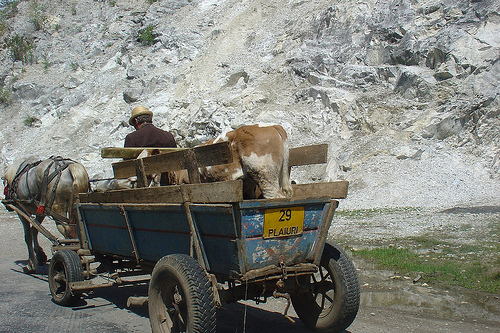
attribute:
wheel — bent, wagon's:
[285, 237, 360, 332]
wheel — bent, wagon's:
[144, 250, 215, 332]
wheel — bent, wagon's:
[46, 246, 86, 304]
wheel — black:
[46, 243, 86, 310]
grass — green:
[350, 235, 498, 297]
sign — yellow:
[246, 163, 328, 258]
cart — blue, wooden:
[45, 139, 359, 329]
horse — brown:
[0, 156, 93, 271]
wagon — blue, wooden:
[74, 182, 368, 326]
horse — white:
[3, 161, 81, 284]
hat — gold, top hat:
[121, 102, 165, 121]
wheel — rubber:
[148, 239, 361, 331]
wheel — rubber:
[47, 248, 141, 305]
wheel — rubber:
[47, 247, 83, 305]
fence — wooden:
[99, 142, 349, 201]